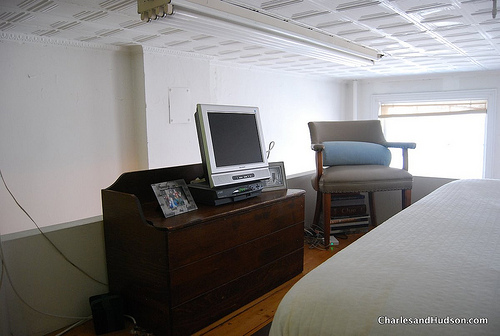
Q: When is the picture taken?
A: Daytime.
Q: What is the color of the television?
A: Grey.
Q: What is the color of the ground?
A: Brown.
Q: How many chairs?
A: 1.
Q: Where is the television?
A: In the table.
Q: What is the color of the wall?
A: White.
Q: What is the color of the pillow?
A: Blue.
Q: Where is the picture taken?
A: In a bedroom.